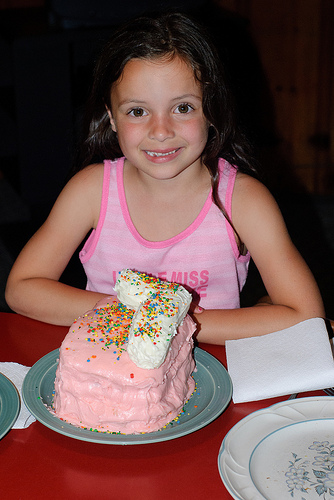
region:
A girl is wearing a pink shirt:
[68, 169, 289, 315]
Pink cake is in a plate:
[30, 332, 241, 439]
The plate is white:
[224, 439, 276, 486]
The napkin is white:
[213, 310, 318, 397]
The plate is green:
[33, 375, 199, 460]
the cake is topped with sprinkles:
[77, 306, 279, 389]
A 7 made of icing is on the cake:
[98, 259, 274, 431]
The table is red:
[27, 433, 142, 490]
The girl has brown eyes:
[89, 96, 263, 121]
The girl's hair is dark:
[87, 28, 167, 96]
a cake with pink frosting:
[57, 304, 187, 438]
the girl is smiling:
[98, 47, 226, 225]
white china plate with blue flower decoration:
[217, 395, 330, 496]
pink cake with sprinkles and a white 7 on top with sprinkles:
[18, 267, 233, 445]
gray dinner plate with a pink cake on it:
[20, 343, 232, 444]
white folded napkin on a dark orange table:
[224, 315, 331, 402]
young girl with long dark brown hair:
[81, 15, 262, 262]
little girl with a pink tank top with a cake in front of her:
[6, 11, 323, 347]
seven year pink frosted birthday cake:
[22, 265, 232, 450]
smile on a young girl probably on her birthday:
[132, 139, 194, 166]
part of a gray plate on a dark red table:
[0, 370, 23, 448]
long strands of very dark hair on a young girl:
[210, 153, 258, 264]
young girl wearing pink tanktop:
[6, 28, 323, 344]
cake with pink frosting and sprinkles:
[50, 301, 200, 430]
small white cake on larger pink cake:
[48, 265, 197, 433]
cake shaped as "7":
[111, 263, 194, 367]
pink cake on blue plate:
[21, 303, 229, 442]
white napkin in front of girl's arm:
[193, 306, 332, 407]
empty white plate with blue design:
[214, 392, 332, 497]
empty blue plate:
[0, 370, 20, 441]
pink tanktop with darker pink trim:
[79, 160, 250, 309]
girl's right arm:
[3, 164, 112, 329]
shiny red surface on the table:
[44, 448, 172, 474]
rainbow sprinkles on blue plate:
[67, 423, 115, 437]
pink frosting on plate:
[83, 381, 143, 404]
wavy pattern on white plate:
[226, 450, 246, 484]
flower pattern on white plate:
[276, 451, 319, 485]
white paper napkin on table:
[225, 330, 323, 400]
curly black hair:
[120, 24, 233, 86]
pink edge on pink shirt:
[117, 221, 203, 251]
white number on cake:
[114, 265, 188, 364]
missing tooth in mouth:
[135, 145, 197, 166]